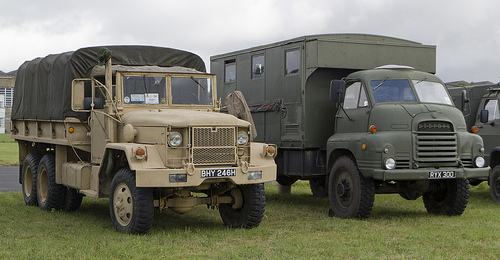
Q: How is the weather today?
A: It is cloudy.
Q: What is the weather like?
A: It is cloudy.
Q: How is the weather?
A: It is cloudy.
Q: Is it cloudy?
A: Yes, it is cloudy.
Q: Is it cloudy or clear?
A: It is cloudy.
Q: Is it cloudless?
A: No, it is cloudy.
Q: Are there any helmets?
A: No, there are no helmets.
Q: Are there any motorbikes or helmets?
A: No, there are no helmets or motorbikes.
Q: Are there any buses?
A: No, there are no buses.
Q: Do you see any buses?
A: No, there are no buses.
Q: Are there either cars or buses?
A: No, there are no buses or cars.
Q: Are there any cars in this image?
A: No, there are no cars.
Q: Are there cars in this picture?
A: No, there are no cars.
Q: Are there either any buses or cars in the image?
A: No, there are no cars or buses.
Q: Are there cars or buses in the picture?
A: No, there are no cars or buses.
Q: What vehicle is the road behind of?
A: The road is behind the truck.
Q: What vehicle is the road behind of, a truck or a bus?
A: The road is behind a truck.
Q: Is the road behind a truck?
A: Yes, the road is behind a truck.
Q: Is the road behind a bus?
A: No, the road is behind a truck.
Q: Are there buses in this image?
A: No, there are no buses.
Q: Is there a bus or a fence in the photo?
A: No, there are no buses or fences.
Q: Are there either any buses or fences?
A: No, there are no buses or fences.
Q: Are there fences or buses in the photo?
A: No, there are no buses or fences.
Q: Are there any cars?
A: No, there are no cars.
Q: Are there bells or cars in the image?
A: No, there are no cars or bells.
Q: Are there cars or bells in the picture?
A: No, there are no cars or bells.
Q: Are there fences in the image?
A: No, there are no fences.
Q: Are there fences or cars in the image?
A: No, there are no fences or cars.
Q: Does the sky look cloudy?
A: Yes, the sky is cloudy.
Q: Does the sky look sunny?
A: No, the sky is cloudy.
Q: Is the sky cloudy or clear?
A: The sky is cloudy.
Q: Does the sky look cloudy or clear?
A: The sky is cloudy.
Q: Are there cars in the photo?
A: No, there are no cars.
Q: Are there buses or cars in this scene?
A: No, there are no cars or buses.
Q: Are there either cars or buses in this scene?
A: No, there are no cars or buses.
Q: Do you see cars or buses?
A: No, there are no cars or buses.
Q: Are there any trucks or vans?
A: Yes, there is a truck.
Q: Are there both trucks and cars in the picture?
A: No, there is a truck but no cars.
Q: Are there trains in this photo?
A: No, there are no trains.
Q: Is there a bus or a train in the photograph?
A: No, there are no trains or buses.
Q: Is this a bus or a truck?
A: This is a truck.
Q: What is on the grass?
A: The truck is on the grass.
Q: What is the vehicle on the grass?
A: The vehicle is a truck.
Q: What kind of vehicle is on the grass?
A: The vehicle is a truck.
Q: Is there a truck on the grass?
A: Yes, there is a truck on the grass.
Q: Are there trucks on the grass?
A: Yes, there is a truck on the grass.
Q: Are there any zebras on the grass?
A: No, there is a truck on the grass.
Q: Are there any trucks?
A: Yes, there is a truck.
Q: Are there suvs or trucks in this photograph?
A: Yes, there is a truck.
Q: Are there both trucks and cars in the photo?
A: No, there is a truck but no cars.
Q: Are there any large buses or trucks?
A: Yes, there is a large truck.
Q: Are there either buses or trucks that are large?
A: Yes, the truck is large.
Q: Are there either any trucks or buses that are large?
A: Yes, the truck is large.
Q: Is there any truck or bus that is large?
A: Yes, the truck is large.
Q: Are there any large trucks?
A: Yes, there is a large truck.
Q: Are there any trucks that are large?
A: Yes, there is a truck that is large.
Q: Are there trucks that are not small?
A: Yes, there is a large truck.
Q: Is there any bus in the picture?
A: No, there are no buses.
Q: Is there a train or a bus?
A: No, there are no buses or trains.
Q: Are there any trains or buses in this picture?
A: No, there are no buses or trains.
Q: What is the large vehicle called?
A: The vehicle is a truck.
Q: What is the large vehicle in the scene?
A: The vehicle is a truck.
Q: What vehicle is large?
A: The vehicle is a truck.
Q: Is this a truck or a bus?
A: This is a truck.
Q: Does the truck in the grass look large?
A: Yes, the truck is large.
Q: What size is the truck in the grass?
A: The truck is large.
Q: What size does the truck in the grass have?
A: The truck has large size.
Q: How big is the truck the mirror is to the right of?
A: The truck is large.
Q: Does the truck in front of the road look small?
A: No, the truck is large.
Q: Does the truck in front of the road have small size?
A: No, the truck is large.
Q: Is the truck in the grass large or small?
A: The truck is large.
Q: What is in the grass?
A: The truck is in the grass.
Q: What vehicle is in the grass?
A: The vehicle is a truck.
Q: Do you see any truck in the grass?
A: Yes, there is a truck in the grass.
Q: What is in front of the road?
A: The truck is in front of the road.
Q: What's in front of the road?
A: The truck is in front of the road.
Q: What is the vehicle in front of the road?
A: The vehicle is a truck.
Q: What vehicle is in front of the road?
A: The vehicle is a truck.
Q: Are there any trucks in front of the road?
A: Yes, there is a truck in front of the road.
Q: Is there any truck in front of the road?
A: Yes, there is a truck in front of the road.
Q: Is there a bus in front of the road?
A: No, there is a truck in front of the road.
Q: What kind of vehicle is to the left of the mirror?
A: The vehicle is a truck.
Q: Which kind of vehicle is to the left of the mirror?
A: The vehicle is a truck.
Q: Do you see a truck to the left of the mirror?
A: Yes, there is a truck to the left of the mirror.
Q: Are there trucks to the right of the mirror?
A: No, the truck is to the left of the mirror.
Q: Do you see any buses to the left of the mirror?
A: No, there is a truck to the left of the mirror.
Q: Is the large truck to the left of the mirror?
A: Yes, the truck is to the left of the mirror.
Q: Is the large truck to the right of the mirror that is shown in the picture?
A: No, the truck is to the left of the mirror.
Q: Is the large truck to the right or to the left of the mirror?
A: The truck is to the left of the mirror.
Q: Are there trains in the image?
A: No, there are no trains.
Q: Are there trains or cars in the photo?
A: No, there are no trains or cars.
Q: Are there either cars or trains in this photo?
A: No, there are no trains or cars.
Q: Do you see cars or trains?
A: No, there are no trains or cars.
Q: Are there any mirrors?
A: Yes, there is a mirror.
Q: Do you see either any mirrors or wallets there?
A: Yes, there is a mirror.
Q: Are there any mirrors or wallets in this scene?
A: Yes, there is a mirror.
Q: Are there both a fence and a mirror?
A: No, there is a mirror but no fences.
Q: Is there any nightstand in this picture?
A: No, there are no nightstands.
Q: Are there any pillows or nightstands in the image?
A: No, there are no nightstands or pillows.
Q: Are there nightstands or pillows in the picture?
A: No, there are no nightstands or pillows.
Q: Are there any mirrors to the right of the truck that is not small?
A: Yes, there is a mirror to the right of the truck.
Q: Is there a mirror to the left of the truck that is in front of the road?
A: No, the mirror is to the right of the truck.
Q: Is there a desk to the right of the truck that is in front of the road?
A: No, there is a mirror to the right of the truck.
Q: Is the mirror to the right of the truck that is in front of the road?
A: Yes, the mirror is to the right of the truck.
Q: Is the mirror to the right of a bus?
A: No, the mirror is to the right of the truck.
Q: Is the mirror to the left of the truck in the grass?
A: No, the mirror is to the right of the truck.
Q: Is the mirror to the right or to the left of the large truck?
A: The mirror is to the right of the truck.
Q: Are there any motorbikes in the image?
A: No, there are no motorbikes.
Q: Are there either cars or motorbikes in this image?
A: No, there are no motorbikes or cars.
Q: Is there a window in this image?
A: Yes, there is a window.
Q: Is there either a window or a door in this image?
A: Yes, there is a window.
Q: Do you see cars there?
A: No, there are no cars.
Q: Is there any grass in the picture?
A: Yes, there is grass.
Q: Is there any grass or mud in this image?
A: Yes, there is grass.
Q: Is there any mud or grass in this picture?
A: Yes, there is grass.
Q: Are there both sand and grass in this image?
A: No, there is grass but no sand.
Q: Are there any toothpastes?
A: No, there are no toothpastes.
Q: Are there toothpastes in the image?
A: No, there are no toothpastes.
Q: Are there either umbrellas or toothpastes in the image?
A: No, there are no toothpastes or umbrellas.